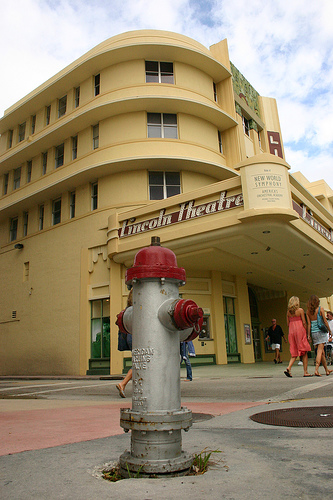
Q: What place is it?
A: It is a theater.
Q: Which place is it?
A: It is a theater.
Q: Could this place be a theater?
A: Yes, it is a theater.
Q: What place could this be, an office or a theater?
A: It is a theater.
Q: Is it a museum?
A: No, it is a theater.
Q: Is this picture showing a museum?
A: No, the picture is showing a theater.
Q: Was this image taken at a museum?
A: No, the picture was taken in a theater.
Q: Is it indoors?
A: Yes, it is indoors.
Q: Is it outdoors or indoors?
A: It is indoors.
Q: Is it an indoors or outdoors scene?
A: It is indoors.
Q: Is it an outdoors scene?
A: No, it is indoors.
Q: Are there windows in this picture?
A: Yes, there is a window.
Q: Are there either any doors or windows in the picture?
A: Yes, there is a window.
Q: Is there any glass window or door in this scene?
A: Yes, there is a glass window.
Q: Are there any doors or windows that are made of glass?
A: Yes, the window is made of glass.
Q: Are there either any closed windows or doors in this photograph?
A: Yes, there is a closed window.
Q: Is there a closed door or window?
A: Yes, there is a closed window.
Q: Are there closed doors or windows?
A: Yes, there is a closed window.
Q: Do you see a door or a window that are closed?
A: Yes, the window is closed.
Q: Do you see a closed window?
A: Yes, there is a closed window.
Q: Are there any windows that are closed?
A: Yes, there is a window that is closed.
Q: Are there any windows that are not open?
A: Yes, there is an closed window.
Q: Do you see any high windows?
A: Yes, there is a high window.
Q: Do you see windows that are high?
A: Yes, there is a window that is high.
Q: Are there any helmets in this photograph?
A: No, there are no helmets.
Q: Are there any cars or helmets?
A: No, there are no helmets or cars.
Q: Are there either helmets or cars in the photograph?
A: No, there are no helmets or cars.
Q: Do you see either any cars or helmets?
A: No, there are no helmets or cars.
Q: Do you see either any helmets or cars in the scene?
A: No, there are no helmets or cars.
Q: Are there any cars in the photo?
A: No, there are no cars.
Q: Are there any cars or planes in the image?
A: No, there are no cars or planes.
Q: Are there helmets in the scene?
A: No, there are no helmets.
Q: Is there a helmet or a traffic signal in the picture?
A: No, there are no helmets or traffic lights.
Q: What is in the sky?
A: The clouds are in the sky.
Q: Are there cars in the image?
A: No, there are no cars.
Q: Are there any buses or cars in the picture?
A: No, there are no cars or buses.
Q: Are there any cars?
A: No, there are no cars.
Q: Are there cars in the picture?
A: No, there are no cars.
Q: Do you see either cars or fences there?
A: No, there are no cars or fences.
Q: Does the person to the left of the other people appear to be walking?
A: Yes, the person is walking.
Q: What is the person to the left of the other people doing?
A: The person is walking.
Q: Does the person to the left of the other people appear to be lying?
A: No, the person is walking.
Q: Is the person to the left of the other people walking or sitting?
A: The person is walking.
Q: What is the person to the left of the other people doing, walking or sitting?
A: The person is walking.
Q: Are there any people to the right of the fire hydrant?
A: Yes, there is a person to the right of the fire hydrant.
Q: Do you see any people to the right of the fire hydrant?
A: Yes, there is a person to the right of the fire hydrant.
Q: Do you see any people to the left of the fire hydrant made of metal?
A: No, the person is to the right of the hydrant.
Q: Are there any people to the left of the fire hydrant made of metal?
A: No, the person is to the right of the hydrant.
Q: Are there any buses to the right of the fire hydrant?
A: No, there is a person to the right of the fire hydrant.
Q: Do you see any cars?
A: No, there are no cars.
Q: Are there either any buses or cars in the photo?
A: No, there are no cars or buses.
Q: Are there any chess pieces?
A: No, there are no chess pieces.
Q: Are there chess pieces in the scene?
A: No, there are no chess pieces.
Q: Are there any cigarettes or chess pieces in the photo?
A: No, there are no chess pieces or cigarettes.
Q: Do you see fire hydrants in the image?
A: Yes, there is a fire hydrant.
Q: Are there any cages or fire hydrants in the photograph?
A: Yes, there is a fire hydrant.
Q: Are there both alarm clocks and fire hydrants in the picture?
A: No, there is a fire hydrant but no alarm clocks.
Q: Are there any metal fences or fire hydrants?
A: Yes, there is a metal fire hydrant.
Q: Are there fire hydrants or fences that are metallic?
A: Yes, the fire hydrant is metallic.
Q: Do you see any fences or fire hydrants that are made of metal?
A: Yes, the fire hydrant is made of metal.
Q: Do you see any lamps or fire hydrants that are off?
A: Yes, the fire hydrant is off.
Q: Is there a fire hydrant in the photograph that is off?
A: Yes, there is a fire hydrant that is off.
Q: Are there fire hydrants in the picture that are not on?
A: Yes, there is a fire hydrant that is off.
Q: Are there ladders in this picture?
A: No, there are no ladders.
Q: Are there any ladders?
A: No, there are no ladders.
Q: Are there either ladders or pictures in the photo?
A: No, there are no ladders or pictures.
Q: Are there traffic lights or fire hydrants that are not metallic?
A: No, there is a fire hydrant but it is metallic.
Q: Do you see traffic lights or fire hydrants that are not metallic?
A: No, there is a fire hydrant but it is metallic.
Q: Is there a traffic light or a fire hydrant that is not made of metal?
A: No, there is a fire hydrant but it is made of metal.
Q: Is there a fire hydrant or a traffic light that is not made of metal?
A: No, there is a fire hydrant but it is made of metal.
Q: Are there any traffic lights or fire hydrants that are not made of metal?
A: No, there is a fire hydrant but it is made of metal.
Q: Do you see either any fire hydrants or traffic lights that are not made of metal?
A: No, there is a fire hydrant but it is made of metal.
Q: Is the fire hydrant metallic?
A: Yes, the fire hydrant is metallic.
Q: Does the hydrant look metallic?
A: Yes, the hydrant is metallic.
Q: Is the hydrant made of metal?
A: Yes, the hydrant is made of metal.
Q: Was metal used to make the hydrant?
A: Yes, the hydrant is made of metal.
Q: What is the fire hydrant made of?
A: The hydrant is made of metal.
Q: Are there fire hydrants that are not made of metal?
A: No, there is a fire hydrant but it is made of metal.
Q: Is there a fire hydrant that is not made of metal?
A: No, there is a fire hydrant but it is made of metal.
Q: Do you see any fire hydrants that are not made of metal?
A: No, there is a fire hydrant but it is made of metal.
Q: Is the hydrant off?
A: Yes, the hydrant is off.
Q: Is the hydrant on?
A: No, the hydrant is off.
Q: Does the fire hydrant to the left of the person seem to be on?
A: No, the hydrant is off.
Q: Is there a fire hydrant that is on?
A: No, there is a fire hydrant but it is off.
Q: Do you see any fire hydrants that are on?
A: No, there is a fire hydrant but it is off.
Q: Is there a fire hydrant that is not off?
A: No, there is a fire hydrant but it is off.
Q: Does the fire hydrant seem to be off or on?
A: The fire hydrant is off.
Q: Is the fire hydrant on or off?
A: The fire hydrant is off.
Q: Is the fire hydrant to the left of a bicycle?
A: No, the fire hydrant is to the left of a person.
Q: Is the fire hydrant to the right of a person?
A: No, the fire hydrant is to the left of a person.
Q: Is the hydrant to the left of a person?
A: Yes, the hydrant is to the left of a person.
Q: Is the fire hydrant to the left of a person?
A: Yes, the fire hydrant is to the left of a person.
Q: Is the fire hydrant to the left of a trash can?
A: No, the fire hydrant is to the left of a person.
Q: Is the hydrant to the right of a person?
A: No, the hydrant is to the left of a person.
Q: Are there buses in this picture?
A: No, there are no buses.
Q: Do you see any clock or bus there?
A: No, there are no buses or clocks.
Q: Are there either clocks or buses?
A: No, there are no buses or clocks.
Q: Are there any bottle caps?
A: No, there are no bottle caps.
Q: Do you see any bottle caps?
A: No, there are no bottle caps.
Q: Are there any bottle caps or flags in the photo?
A: No, there are no bottle caps or flags.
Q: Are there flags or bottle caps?
A: No, there are no bottle caps or flags.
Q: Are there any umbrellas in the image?
A: No, there are no umbrellas.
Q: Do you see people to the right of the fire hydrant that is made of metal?
A: Yes, there are people to the right of the hydrant.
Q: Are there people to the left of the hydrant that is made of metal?
A: No, the people are to the right of the hydrant.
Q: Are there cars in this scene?
A: No, there are no cars.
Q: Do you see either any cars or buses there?
A: No, there are no cars or buses.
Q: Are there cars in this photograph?
A: No, there are no cars.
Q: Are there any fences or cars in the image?
A: No, there are no cars or fences.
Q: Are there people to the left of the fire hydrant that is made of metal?
A: No, the person is to the right of the hydrant.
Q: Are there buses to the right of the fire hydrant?
A: No, there is a person to the right of the fire hydrant.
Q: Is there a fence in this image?
A: No, there are no fences.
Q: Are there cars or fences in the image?
A: No, there are no fences or cars.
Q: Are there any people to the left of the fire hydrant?
A: No, the person is to the right of the fire hydrant.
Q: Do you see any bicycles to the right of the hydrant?
A: No, there is a person to the right of the hydrant.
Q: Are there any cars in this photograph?
A: No, there are no cars.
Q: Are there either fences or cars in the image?
A: No, there are no cars or fences.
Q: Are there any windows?
A: Yes, there is a window.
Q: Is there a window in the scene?
A: Yes, there is a window.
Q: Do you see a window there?
A: Yes, there is a window.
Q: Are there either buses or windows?
A: Yes, there is a window.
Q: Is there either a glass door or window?
A: Yes, there is a glass window.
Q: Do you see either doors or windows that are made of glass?
A: Yes, the window is made of glass.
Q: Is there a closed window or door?
A: Yes, there is a closed window.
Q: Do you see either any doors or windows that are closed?
A: Yes, the window is closed.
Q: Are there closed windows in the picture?
A: Yes, there is a closed window.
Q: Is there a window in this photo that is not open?
A: Yes, there is an closed window.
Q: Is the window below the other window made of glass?
A: Yes, the window is made of glass.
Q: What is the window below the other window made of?
A: The window is made of glass.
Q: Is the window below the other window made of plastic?
A: No, the window is made of glass.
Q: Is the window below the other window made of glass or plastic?
A: The window is made of glass.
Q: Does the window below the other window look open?
A: No, the window is closed.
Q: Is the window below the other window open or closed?
A: The window is closed.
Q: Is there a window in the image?
A: Yes, there is a window.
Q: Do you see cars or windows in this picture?
A: Yes, there is a window.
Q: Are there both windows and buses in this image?
A: No, there is a window but no buses.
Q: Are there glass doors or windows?
A: Yes, there is a glass window.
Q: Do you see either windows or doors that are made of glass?
A: Yes, the window is made of glass.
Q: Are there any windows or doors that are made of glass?
A: Yes, the window is made of glass.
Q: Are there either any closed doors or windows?
A: Yes, there is a closed window.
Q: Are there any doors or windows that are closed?
A: Yes, the window is closed.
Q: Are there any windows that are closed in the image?
A: Yes, there is a closed window.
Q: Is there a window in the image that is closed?
A: Yes, there is a closed window.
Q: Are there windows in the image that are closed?
A: Yes, there is a window that is closed.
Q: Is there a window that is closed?
A: Yes, there is a window that is closed.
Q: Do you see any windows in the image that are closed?
A: Yes, there is a window that is closed.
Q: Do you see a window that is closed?
A: Yes, there is a window that is closed.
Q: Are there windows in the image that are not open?
A: Yes, there is an closed window.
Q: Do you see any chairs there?
A: No, there are no chairs.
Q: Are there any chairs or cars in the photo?
A: No, there are no chairs or cars.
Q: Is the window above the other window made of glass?
A: Yes, the window is made of glass.